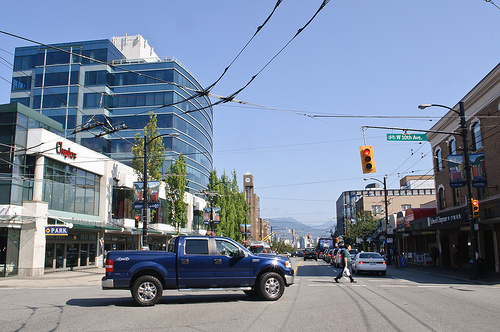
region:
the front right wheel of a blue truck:
[254, 262, 289, 306]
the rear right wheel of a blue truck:
[129, 270, 169, 309]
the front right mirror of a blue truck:
[230, 240, 248, 265]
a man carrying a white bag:
[337, 261, 358, 286]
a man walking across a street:
[334, 237, 359, 289]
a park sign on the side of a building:
[38, 216, 73, 241]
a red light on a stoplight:
[355, 138, 384, 180]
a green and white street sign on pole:
[376, 127, 430, 150]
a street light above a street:
[408, 95, 447, 118]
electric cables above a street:
[165, 62, 275, 126]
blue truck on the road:
[96, 232, 298, 307]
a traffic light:
[357, 140, 378, 176]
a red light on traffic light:
[362, 146, 370, 156]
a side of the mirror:
[235, 245, 245, 256]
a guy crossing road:
[333, 242, 357, 284]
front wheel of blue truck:
[257, 269, 287, 301]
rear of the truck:
[130, 270, 165, 307]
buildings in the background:
[3, 30, 272, 280]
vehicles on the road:
[300, 242, 388, 277]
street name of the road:
[384, 130, 429, 144]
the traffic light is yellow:
[350, 137, 376, 177]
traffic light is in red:
[353, 135, 379, 180]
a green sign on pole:
[377, 121, 436, 145]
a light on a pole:
[413, 93, 476, 192]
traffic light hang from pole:
[467, 195, 482, 215]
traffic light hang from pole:
[130, 207, 150, 236]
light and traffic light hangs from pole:
[123, 127, 182, 244]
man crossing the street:
[330, 237, 364, 288]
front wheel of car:
[251, 265, 297, 304]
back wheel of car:
[127, 271, 165, 310]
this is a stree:
[26, 130, 496, 312]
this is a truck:
[150, 235, 287, 295]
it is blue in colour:
[157, 237, 294, 294]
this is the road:
[302, 292, 391, 317]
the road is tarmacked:
[298, 292, 382, 328]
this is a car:
[355, 252, 383, 272]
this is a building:
[14, 151, 99, 249]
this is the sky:
[270, 158, 327, 212]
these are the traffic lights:
[355, 145, 379, 181]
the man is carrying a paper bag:
[340, 245, 355, 287]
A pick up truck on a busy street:
[92, 223, 304, 310]